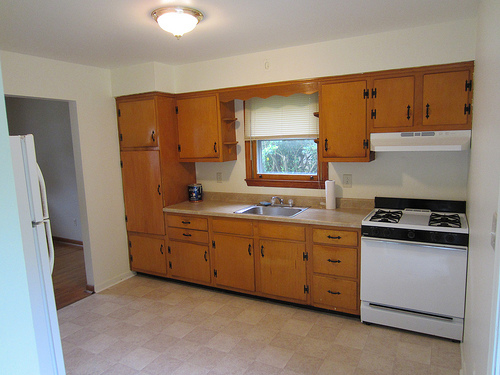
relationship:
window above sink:
[251, 97, 319, 173] [239, 195, 304, 222]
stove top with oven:
[368, 201, 475, 240] [362, 240, 464, 324]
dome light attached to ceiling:
[151, 7, 203, 42] [1, 0, 485, 65]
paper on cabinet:
[323, 177, 339, 209] [116, 60, 475, 315]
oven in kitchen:
[359, 208, 470, 342] [0, 0, 498, 375]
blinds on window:
[243, 92, 319, 142] [249, 103, 319, 174]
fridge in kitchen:
[2, 133, 70, 373] [0, 0, 498, 375]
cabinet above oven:
[369, 60, 475, 134] [359, 208, 470, 342]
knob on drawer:
[322, 229, 347, 239] [312, 229, 358, 246]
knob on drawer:
[323, 253, 342, 263] [312, 242, 361, 280]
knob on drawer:
[320, 283, 344, 297] [308, 270, 360, 313]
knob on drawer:
[179, 216, 197, 221] [162, 210, 212, 230]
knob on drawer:
[323, 230, 343, 240] [308, 223, 360, 247]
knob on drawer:
[324, 251, 343, 261] [306, 243, 359, 281]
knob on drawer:
[322, 286, 342, 295] [308, 270, 360, 313]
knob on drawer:
[178, 216, 194, 224] [164, 212, 210, 229]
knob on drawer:
[176, 227, 192, 235] [162, 223, 212, 245]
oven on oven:
[358, 221, 469, 321] [359, 208, 470, 342]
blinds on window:
[243, 92, 319, 142] [251, 92, 319, 179]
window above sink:
[251, 92, 319, 179] [230, 202, 300, 218]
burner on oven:
[370, 210, 403, 223] [359, 208, 470, 342]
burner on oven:
[428, 212, 461, 227] [359, 208, 470, 342]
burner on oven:
[425, 208, 463, 220] [359, 208, 470, 342]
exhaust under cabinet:
[366, 129, 475, 155] [369, 60, 475, 134]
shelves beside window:
[219, 93, 238, 157] [245, 98, 318, 175]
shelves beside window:
[313, 93, 322, 147] [245, 98, 318, 175]